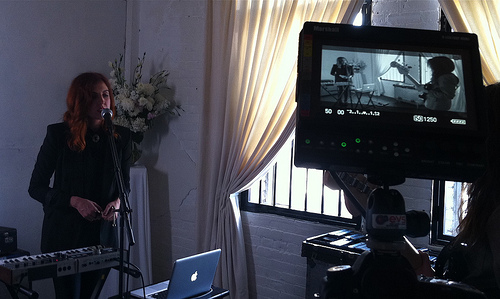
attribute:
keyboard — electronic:
[3, 244, 127, 279]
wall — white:
[130, 0, 233, 264]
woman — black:
[417, 58, 470, 110]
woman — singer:
[1, 49, 196, 297]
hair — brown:
[59, 92, 92, 154]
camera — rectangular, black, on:
[290, 19, 492, 183]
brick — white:
[254, 234, 283, 251]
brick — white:
[169, 233, 198, 249]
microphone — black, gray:
[98, 102, 126, 143]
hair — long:
[67, 71, 94, 144]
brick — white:
[183, 196, 192, 208]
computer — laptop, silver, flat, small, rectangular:
[153, 245, 230, 295]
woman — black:
[11, 64, 160, 297]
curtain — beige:
[194, 2, 499, 290]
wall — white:
[244, 204, 354, 287]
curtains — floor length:
[201, 0, 499, 297]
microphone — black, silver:
[97, 104, 127, 194]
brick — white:
[132, 3, 204, 229]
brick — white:
[256, 221, 301, 240]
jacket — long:
[28, 118, 129, 268]